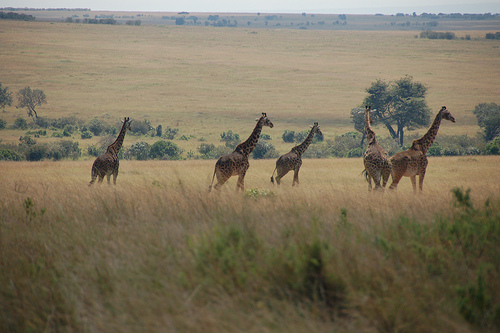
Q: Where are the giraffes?
A: Savannah.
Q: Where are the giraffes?
A: In the field.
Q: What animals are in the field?
A: Giraffes.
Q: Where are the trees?
A: In the field.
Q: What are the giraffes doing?
A: Walking.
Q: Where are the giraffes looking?
A: Forward.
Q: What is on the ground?
A: High grass.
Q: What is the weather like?
A: Clear.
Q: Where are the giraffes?
A: In front of the trees.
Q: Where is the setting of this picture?
A: A field.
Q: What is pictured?
A: A group of giraffes.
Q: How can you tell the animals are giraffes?
A: Long neck.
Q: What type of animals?
A: Giraffes.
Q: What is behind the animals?
A: A pasture.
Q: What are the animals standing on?
A: Dead grass.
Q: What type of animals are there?
A: Giraffes.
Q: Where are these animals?
A: In the wild.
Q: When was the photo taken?
A: Daytime.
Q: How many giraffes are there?
A: Five.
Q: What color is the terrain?
A: Green and yellow.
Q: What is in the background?
A: Land.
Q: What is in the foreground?
A: Terrain.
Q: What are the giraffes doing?
A: Walking together.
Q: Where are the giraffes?
A: In the tall grass.